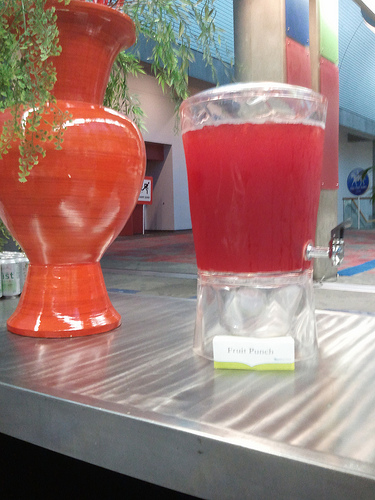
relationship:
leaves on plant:
[1, 0, 237, 186] [0, 0, 235, 186]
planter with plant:
[6, 40, 135, 354] [3, 109, 79, 190]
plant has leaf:
[0, 0, 74, 186] [168, 53, 176, 66]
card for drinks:
[208, 330, 299, 373] [179, 121, 324, 277]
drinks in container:
[179, 121, 324, 277] [178, 80, 345, 363]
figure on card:
[141, 181, 151, 194] [213, 335, 294, 372]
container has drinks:
[172, 71, 335, 371] [179, 121, 324, 277]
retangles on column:
[279, 1, 344, 91] [283, 0, 342, 88]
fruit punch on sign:
[221, 341, 282, 360] [212, 331, 297, 371]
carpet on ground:
[109, 241, 197, 277] [111, 230, 196, 281]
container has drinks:
[178, 80, 345, 363] [179, 121, 324, 277]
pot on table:
[0, 0, 147, 340] [71, 358, 236, 475]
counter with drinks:
[88, 376, 227, 460] [196, 59, 332, 320]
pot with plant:
[11, 186, 128, 327] [4, 21, 61, 146]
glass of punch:
[215, 282, 282, 309] [213, 171, 265, 230]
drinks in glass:
[179, 121, 324, 277] [177, 80, 344, 359]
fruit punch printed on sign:
[226, 346, 277, 358] [212, 331, 297, 371]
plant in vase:
[0, 0, 235, 186] [2, 4, 149, 346]